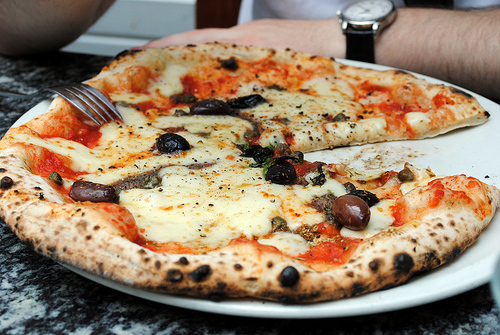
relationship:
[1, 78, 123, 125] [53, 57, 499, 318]
fork resting on plate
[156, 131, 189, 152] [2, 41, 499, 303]
black olive on top of pizza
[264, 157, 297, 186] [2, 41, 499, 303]
black olive on top of pizza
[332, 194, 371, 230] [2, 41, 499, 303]
black olive on top of pizza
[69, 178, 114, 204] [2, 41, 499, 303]
black olive on top of pizza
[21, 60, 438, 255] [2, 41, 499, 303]
cheese on top of pizza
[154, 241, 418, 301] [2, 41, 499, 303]
burnt spots on crust of pizza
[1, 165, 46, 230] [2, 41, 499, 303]
burnt spots on crust of pizza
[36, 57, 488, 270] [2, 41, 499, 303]
tomato sauce on top of pizza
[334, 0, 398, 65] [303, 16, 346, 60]
watch around wrist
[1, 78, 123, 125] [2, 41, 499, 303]
fork resting on pizza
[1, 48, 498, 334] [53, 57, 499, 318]
counter top underneath plate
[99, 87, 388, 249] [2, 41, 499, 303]
seasoning on top of pizza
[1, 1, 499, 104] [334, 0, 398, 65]
person wearing watch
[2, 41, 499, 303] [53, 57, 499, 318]
pizza on top of plate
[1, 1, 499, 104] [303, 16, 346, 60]
person has wrist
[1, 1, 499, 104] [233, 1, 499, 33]
person wearing shirt